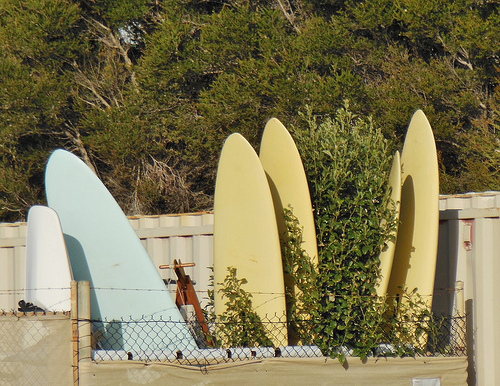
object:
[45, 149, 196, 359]
surfboard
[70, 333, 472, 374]
planter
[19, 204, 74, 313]
surfboard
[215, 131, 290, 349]
surfboards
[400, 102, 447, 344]
surfboards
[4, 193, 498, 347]
wall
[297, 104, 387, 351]
bush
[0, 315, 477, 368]
fence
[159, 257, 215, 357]
pulley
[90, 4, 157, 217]
trees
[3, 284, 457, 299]
barbed wire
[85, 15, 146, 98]
branches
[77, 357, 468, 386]
tarp